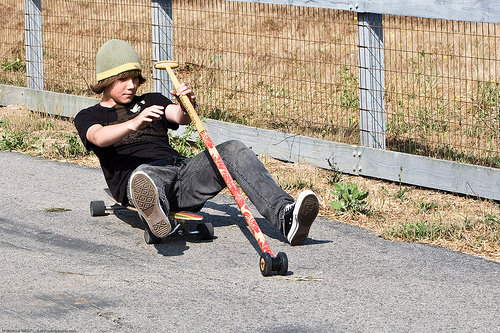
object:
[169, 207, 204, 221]
tip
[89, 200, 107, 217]
wheel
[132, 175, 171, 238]
tread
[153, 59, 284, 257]
pole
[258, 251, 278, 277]
wheel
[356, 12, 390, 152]
post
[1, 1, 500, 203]
fencing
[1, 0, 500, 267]
grass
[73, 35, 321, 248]
guy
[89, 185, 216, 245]
skateboard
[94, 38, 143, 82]
cap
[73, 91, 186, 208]
t-shirt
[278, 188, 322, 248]
sneaker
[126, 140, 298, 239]
jeans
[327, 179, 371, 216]
weed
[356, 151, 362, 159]
bolt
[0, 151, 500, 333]
pavement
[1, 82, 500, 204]
wood